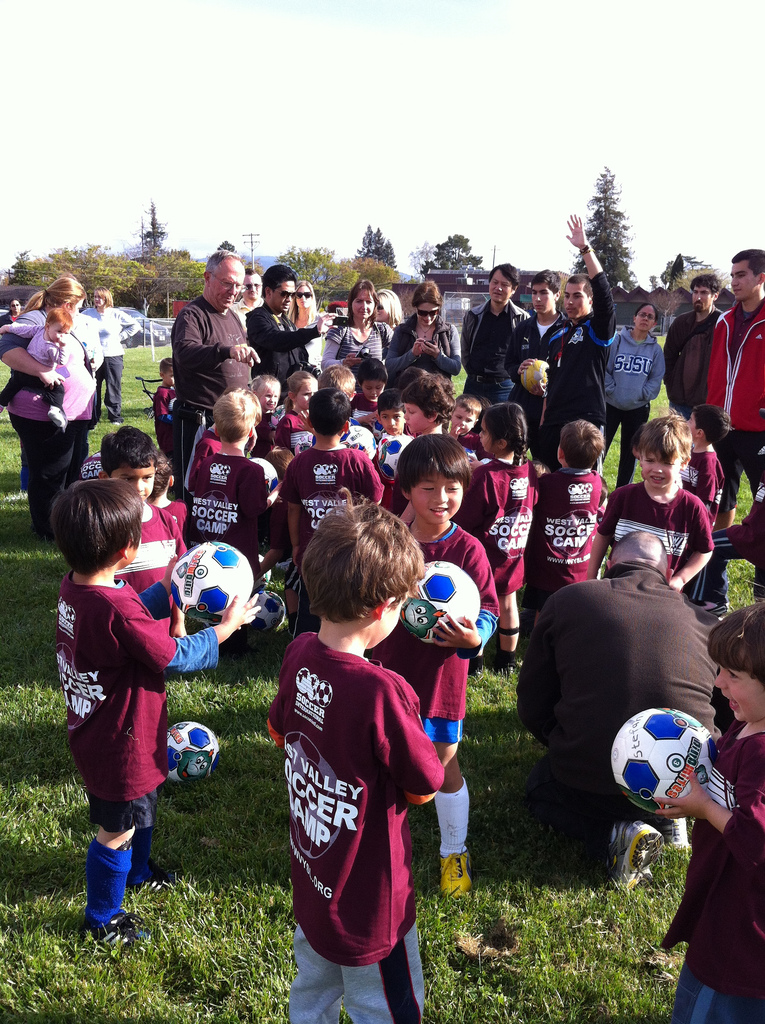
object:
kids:
[51, 361, 764, 1023]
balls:
[168, 539, 286, 632]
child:
[46, 482, 268, 951]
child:
[654, 605, 763, 1022]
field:
[0, 351, 763, 1022]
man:
[537, 224, 616, 473]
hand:
[566, 214, 587, 249]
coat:
[705, 296, 765, 433]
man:
[683, 247, 765, 616]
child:
[266, 492, 475, 1021]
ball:
[610, 707, 719, 816]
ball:
[397, 559, 482, 646]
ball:
[169, 539, 253, 622]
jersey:
[265, 632, 446, 968]